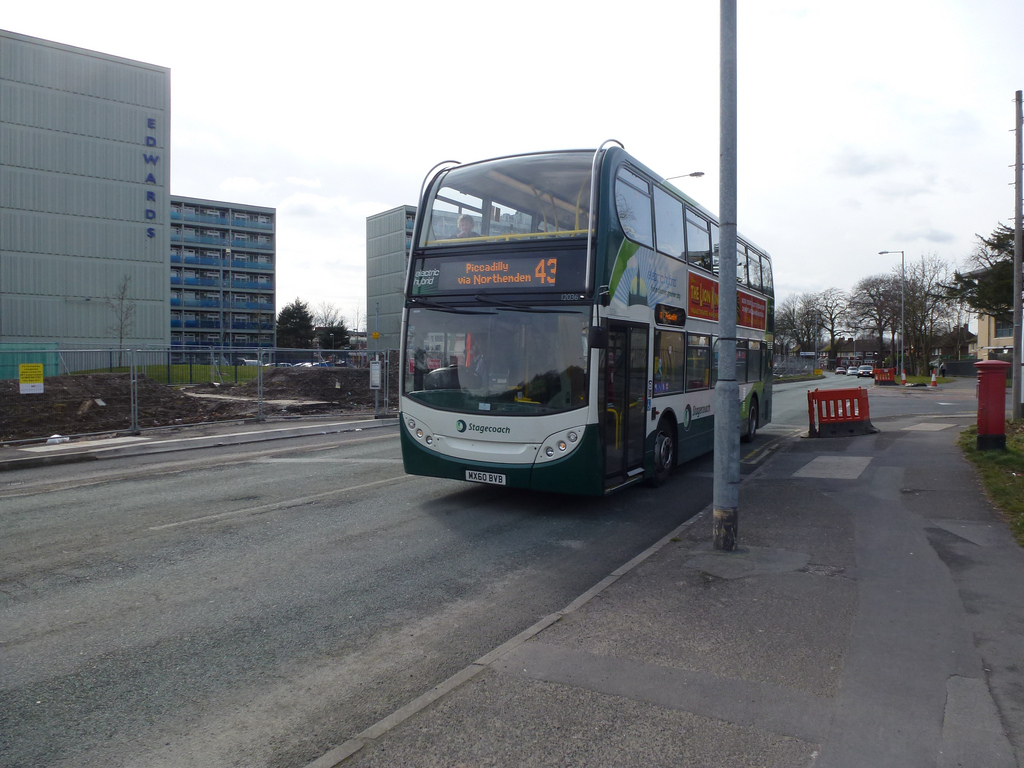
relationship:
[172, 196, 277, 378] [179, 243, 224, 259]
building with balcony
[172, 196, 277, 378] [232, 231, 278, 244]
building with balcony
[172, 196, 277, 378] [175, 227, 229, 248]
building with balcony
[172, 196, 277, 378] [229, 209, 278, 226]
building with balcony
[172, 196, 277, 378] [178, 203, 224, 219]
building with balcony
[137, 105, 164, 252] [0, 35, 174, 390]
word on wall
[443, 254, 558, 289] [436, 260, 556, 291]
characters on sign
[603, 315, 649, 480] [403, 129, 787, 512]
door on bus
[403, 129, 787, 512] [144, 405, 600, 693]
bus on street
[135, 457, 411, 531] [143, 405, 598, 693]
lines in street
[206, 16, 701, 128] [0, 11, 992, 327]
clouds in sky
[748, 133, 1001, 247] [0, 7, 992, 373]
clouds in sky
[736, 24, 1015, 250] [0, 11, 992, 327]
clouds in sky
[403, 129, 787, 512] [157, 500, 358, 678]
bus on road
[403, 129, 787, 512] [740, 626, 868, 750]
bus near sidewalk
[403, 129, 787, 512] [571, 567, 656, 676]
bus near curb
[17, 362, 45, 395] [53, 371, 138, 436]
sign on fence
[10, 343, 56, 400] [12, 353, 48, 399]
sign on fence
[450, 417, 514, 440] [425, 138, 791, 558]
writing on bus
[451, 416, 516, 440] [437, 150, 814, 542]
letters on bus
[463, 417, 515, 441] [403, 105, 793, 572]
letters on front bus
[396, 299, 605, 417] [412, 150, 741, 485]
windshield of a bus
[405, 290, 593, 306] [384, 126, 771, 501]
wipers of a bus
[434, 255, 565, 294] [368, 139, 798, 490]
sign of a bus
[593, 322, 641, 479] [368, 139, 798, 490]
door of a bus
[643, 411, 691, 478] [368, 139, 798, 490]
wheel on bus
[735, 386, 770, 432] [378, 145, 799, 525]
wheel of bus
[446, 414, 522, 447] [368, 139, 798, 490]
logo of bus